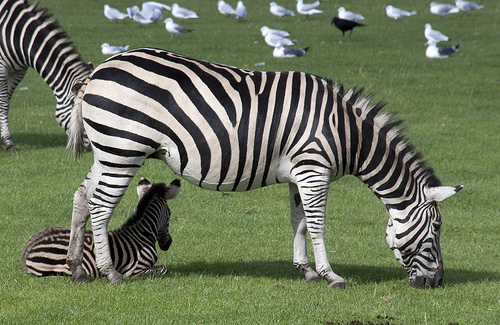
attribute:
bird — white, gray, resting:
[420, 38, 467, 60]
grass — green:
[387, 64, 498, 114]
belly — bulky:
[149, 120, 289, 200]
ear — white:
[424, 182, 462, 200]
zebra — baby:
[20, 170, 183, 287]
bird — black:
[322, 10, 379, 42]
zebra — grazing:
[1, 0, 91, 151]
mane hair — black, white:
[327, 74, 445, 186]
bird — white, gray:
[423, 40, 468, 62]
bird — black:
[328, 14, 368, 41]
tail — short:
[66, 70, 91, 152]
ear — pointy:
[420, 177, 465, 204]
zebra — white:
[86, 58, 455, 292]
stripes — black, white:
[60, 47, 465, 287]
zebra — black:
[66, 42, 464, 292]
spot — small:
[284, 184, 323, 285]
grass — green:
[2, 5, 496, 323]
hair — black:
[349, 83, 445, 193]